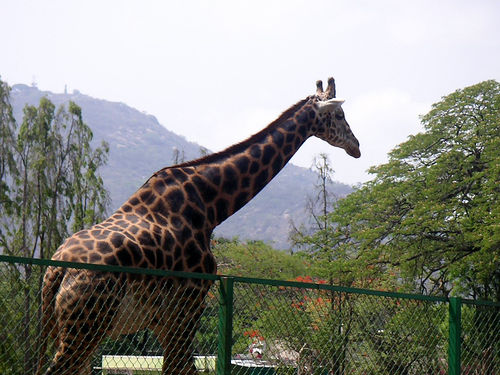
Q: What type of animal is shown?
A: A giraffe.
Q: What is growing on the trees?
A: Leaves.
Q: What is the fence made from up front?
A: Metal.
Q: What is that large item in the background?
A: A mountain.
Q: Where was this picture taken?
A: At the zoo.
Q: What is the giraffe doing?
A: Standing in his pen.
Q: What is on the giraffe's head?
A: Horns.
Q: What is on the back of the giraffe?
A: A tail.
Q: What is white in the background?
A: The building.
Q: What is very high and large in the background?
A: The hills.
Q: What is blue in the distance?
A: The sky.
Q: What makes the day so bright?
A: The sun.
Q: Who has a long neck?
A: The giraffe.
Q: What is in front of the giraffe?
A: A fence.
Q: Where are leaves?
A: On trees.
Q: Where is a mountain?
A: In the distance.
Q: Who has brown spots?
A: Giraffe.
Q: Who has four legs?
A: A giraffe.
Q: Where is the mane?
A: On giraffe's neck.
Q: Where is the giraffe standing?
A: Behind the fence.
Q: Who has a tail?
A: Giraffe.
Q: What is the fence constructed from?
A: Metal.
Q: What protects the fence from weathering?
A: Paint.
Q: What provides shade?
A: Trees.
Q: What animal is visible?
A: Giraffe.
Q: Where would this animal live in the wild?
A: Africa.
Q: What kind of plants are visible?
A: Trees.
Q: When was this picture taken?
A: Daytime.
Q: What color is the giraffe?
A: Brown and white.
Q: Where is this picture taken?
A: The zoo.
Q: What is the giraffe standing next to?
A: Trees.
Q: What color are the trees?
A: Green.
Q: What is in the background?
A: The mountainside.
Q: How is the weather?
A: Clear.